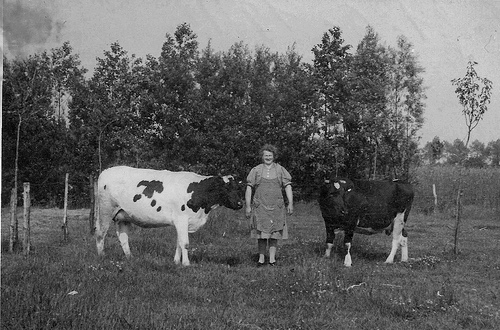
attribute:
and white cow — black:
[78, 134, 242, 286]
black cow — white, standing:
[296, 151, 439, 284]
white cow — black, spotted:
[81, 149, 258, 270]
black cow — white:
[299, 141, 422, 275]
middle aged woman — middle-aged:
[238, 121, 299, 270]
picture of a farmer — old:
[217, 122, 310, 275]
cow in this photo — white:
[76, 160, 250, 270]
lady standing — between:
[239, 137, 307, 271]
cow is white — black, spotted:
[83, 116, 249, 287]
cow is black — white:
[316, 155, 414, 276]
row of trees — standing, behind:
[4, 12, 423, 189]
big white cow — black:
[88, 165, 244, 272]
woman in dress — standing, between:
[233, 151, 320, 267]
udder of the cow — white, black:
[108, 206, 130, 238]